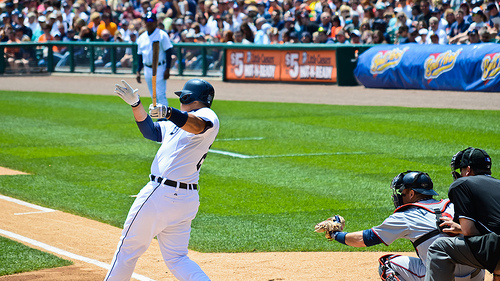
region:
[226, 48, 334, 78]
LITTLE CESAR'S HOT AND READY PIZZA SIGN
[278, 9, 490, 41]
BASEBALL FANS IN STANDS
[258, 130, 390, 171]
GREEN ASTROTURF OF BASEBALL FIELD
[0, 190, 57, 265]
WHITE BASEBALL DIAMOND MARKINGS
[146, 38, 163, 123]
BASEBALL BAT IN GLOVED HAND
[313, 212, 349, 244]
BROWN CATCHERS MITT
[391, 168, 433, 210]
CATCHER'S FACE MASK, AND HELMET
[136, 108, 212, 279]
BLUE AND WHITE BASEBALL UNIFORM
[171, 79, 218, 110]
BLUE BATTER'S HELMET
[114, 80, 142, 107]
WHITE BATTER'S GLOVE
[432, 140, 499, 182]
a black umpire's mask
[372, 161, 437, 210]
a black catcher's mask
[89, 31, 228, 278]
a player swinging a bat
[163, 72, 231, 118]
a black baseball helmet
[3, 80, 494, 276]
a grassy ballpark infield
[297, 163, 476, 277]
a catcher prepares for the ball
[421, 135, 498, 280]
an umpire watching a pitch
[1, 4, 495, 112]
crowd watching a ball game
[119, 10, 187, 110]
baseball coach watches game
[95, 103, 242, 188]
a white baseball jersey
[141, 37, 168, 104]
baseball bat in players hands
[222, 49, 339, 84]
little cesars advertisement on the sidelines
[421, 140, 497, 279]
The umpire is behind the catcher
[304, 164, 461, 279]
the catcher is in the processes of catching the ball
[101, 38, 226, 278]
baseball player in full swing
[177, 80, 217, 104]
helmet that batters where while at bat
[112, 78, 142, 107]
gloves that are worn when up at bat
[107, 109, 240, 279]
baseball uniform is white and blue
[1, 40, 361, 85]
fence between spectators and players in the field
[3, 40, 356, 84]
the fence that separates the fans from the players is green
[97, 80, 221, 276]
the man is playing baseball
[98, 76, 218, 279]
the man is batting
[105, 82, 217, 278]
the man is wearing a white uniform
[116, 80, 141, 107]
the man is wearing a glove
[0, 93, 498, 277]
the grass is green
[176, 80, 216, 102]
the man is wearing a helmet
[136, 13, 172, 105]
the man is wearing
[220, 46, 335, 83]
the sign says "$5"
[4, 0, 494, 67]
people are watching the game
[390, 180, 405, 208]
the man has a face mask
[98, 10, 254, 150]
team member standing behind hitter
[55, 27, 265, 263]
hitter with bat to his left side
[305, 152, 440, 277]
catcher with left arm extended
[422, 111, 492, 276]
umpire crouched behind catcher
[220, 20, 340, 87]
identical orange and white signs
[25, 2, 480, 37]
spectators close to the baseball field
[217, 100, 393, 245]
thick green grass with lighter wide stripes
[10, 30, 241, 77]
metal railing in front of spectators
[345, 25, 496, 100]
repeated logo on rolled tarp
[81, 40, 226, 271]
batter leading with left foot